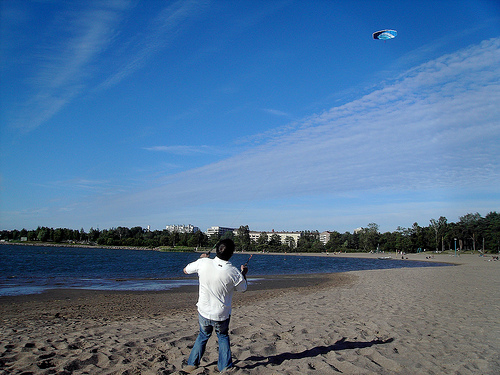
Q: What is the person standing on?
A: The beach.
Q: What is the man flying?
A: A kite.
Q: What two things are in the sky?
A: Clouds and a kite.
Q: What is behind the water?
A: Trees.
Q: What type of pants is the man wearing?
A: Blue jeans.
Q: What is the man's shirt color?
A: White.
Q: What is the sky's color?
A: Blue.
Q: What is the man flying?
A: Kite.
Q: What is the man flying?
A: Kite.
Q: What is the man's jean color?
A: Blue.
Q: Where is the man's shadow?
A: The beach.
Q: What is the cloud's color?
A: White.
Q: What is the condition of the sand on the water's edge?
A: Wet.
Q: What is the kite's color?
A: Blue.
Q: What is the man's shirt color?
A: White.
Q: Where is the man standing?
A: On the sand.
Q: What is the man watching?
A: A wind surfer.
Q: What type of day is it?
A: A sunny day.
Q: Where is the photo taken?
A: The beach.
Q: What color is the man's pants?
A: Blue.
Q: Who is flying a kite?
A: The man.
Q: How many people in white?
A: One.